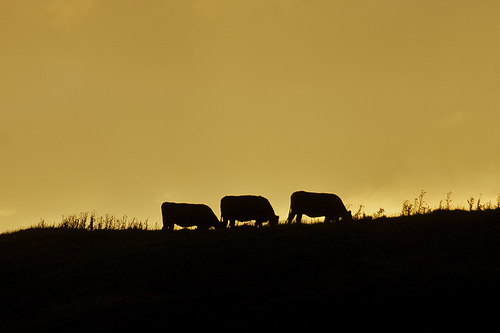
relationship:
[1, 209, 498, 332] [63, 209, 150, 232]
hill has grass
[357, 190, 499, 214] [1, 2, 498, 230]
cloud in sky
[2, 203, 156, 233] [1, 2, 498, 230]
cloud in sky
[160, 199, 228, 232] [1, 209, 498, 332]
cows on hill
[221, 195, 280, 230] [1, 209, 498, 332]
cow on hill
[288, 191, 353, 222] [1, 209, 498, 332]
cow on hill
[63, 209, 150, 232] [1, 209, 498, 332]
grass on hill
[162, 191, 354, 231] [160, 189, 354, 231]
shadow of cows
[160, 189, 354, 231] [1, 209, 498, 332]
cows on hill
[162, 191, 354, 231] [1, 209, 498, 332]
shadow on hill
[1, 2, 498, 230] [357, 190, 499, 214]
sky has cloud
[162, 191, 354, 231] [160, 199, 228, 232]
shadow of cows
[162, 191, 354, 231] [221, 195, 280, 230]
shadow of cow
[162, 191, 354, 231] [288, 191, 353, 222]
shadow of cow